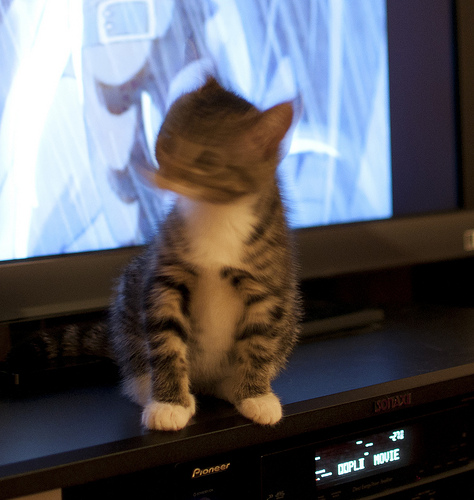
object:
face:
[160, 101, 254, 195]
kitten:
[112, 73, 301, 431]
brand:
[190, 463, 231, 478]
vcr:
[62, 391, 473, 500]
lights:
[313, 426, 407, 481]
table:
[2, 303, 473, 499]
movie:
[1, 0, 391, 259]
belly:
[186, 193, 237, 365]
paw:
[141, 392, 196, 430]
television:
[0, 0, 473, 337]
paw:
[235, 392, 282, 426]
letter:
[373, 454, 380, 466]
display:
[312, 424, 414, 486]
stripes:
[143, 275, 193, 319]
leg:
[140, 257, 199, 432]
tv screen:
[1, 1, 465, 263]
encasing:
[1, 0, 473, 323]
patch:
[177, 193, 265, 260]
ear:
[260, 100, 293, 151]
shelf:
[363, 460, 472, 500]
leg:
[227, 267, 285, 424]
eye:
[198, 149, 221, 167]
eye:
[159, 129, 175, 154]